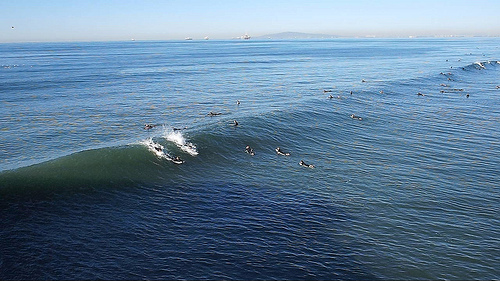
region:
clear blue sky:
[0, 0, 498, 27]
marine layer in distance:
[0, 25, 498, 39]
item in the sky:
[9, 22, 21, 33]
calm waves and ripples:
[199, 193, 499, 276]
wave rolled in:
[1, 114, 224, 199]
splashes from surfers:
[148, 128, 196, 162]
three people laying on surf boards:
[243, 142, 316, 173]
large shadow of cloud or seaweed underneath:
[13, 172, 375, 277]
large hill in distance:
[268, 30, 310, 38]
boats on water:
[184, 33, 216, 46]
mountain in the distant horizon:
[218, 25, 491, 40]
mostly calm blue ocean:
[5, 37, 497, 279]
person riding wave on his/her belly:
[144, 134, 184, 172]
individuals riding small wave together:
[133, 57, 498, 173]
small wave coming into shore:
[8, 51, 499, 196]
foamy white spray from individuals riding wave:
[136, 125, 196, 165]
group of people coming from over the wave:
[226, 116, 311, 176]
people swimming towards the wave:
[136, 100, 221, 130]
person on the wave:
[224, 119, 244, 129]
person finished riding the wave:
[296, 158, 318, 173]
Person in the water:
[299, 157, 312, 171]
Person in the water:
[272, 146, 292, 158]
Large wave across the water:
[0, 54, 495, 209]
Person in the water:
[229, 116, 241, 130]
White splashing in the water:
[164, 127, 194, 154]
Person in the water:
[348, 112, 363, 123]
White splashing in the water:
[144, 133, 184, 167]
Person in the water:
[414, 87, 422, 97]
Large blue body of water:
[2, 40, 494, 278]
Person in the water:
[234, 97, 244, 107]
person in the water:
[298, 157, 313, 169]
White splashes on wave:
[141, 138, 173, 163]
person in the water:
[243, 144, 256, 155]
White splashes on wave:
[166, 129, 203, 153]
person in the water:
[274, 145, 291, 157]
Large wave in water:
[0, 58, 499, 198]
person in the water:
[234, 96, 241, 105]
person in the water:
[346, 108, 361, 120]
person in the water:
[416, 90, 423, 97]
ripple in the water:
[420, 202, 437, 216]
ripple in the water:
[242, 228, 268, 255]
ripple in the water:
[286, 245, 313, 274]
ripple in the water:
[416, 244, 433, 268]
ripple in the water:
[240, 237, 262, 255]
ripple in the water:
[385, 195, 419, 231]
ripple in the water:
[287, 247, 302, 264]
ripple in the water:
[467, 236, 489, 260]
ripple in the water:
[302, 218, 317, 231]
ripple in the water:
[316, 210, 373, 269]